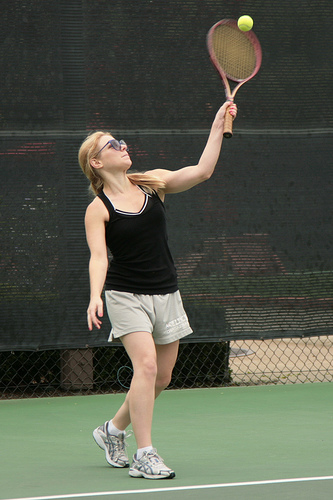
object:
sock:
[136, 450, 153, 458]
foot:
[129, 445, 178, 482]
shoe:
[94, 420, 129, 471]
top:
[97, 182, 180, 294]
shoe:
[129, 449, 174, 481]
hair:
[77, 127, 165, 195]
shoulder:
[126, 167, 165, 205]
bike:
[103, 419, 124, 438]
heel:
[89, 422, 105, 452]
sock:
[107, 419, 121, 437]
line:
[2, 475, 331, 499]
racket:
[205, 13, 268, 134]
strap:
[98, 194, 112, 208]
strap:
[140, 187, 156, 193]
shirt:
[95, 179, 179, 292]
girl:
[78, 98, 240, 479]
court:
[0, 0, 333, 500]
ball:
[237, 10, 254, 34]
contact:
[212, 18, 255, 78]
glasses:
[106, 139, 126, 149]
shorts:
[104, 289, 192, 350]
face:
[98, 132, 133, 170]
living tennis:
[204, 13, 271, 141]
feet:
[87, 416, 127, 468]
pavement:
[228, 336, 333, 388]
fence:
[0, 0, 333, 398]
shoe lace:
[143, 446, 164, 462]